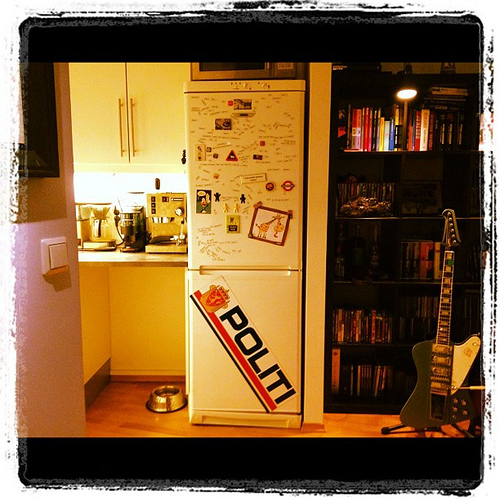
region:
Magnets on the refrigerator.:
[188, 92, 302, 264]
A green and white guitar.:
[397, 197, 481, 434]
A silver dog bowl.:
[137, 371, 191, 428]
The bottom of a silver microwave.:
[183, 62, 308, 80]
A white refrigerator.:
[178, 80, 306, 431]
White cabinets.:
[67, 62, 188, 166]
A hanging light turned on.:
[389, 65, 427, 107]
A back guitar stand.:
[364, 378, 474, 445]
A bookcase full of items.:
[324, 68, 473, 413]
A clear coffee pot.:
[86, 214, 116, 245]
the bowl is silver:
[108, 341, 202, 448]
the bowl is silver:
[131, 337, 231, 474]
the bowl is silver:
[73, 333, 191, 495]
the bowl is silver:
[90, 278, 282, 493]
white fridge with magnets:
[172, 72, 309, 432]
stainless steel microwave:
[177, 52, 318, 90]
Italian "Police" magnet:
[187, 270, 302, 415]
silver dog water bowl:
[138, 385, 186, 420]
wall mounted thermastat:
[36, 229, 77, 284]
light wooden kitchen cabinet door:
[70, 65, 187, 171]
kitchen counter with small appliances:
[78, 176, 185, 273]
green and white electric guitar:
[376, 192, 477, 438]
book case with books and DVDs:
[326, 55, 486, 437]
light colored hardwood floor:
[105, 388, 220, 433]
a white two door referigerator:
[182, 80, 307, 427]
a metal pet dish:
[147, 382, 187, 414]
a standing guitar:
[393, 208, 486, 437]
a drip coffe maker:
[113, 188, 143, 253]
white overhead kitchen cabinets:
[70, 63, 186, 166]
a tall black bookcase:
[320, 60, 476, 407]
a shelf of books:
[340, 92, 475, 152]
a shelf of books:
[332, 168, 472, 213]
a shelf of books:
[338, 233, 474, 278]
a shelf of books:
[327, 297, 474, 345]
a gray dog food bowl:
[146, 381, 186, 411]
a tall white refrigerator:
[180, 79, 305, 428]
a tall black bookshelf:
[323, 73, 498, 413]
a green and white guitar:
[396, 205, 480, 431]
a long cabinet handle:
[126, 95, 141, 159]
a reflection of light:
[75, 175, 181, 206]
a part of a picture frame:
[20, 89, 66, 183]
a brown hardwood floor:
[86, 378, 468, 436]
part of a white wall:
[300, 60, 333, 428]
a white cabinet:
[115, 266, 190, 376]